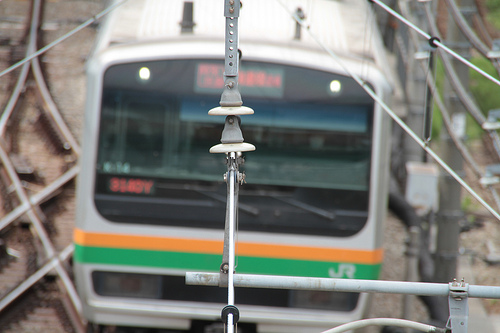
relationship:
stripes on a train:
[83, 224, 381, 298] [65, 19, 435, 331]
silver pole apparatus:
[220, 70, 251, 333] [219, 174, 249, 244]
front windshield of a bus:
[77, 197, 347, 251] [78, 101, 448, 273]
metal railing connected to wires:
[232, 275, 449, 295] [426, 127, 486, 280]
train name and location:
[168, 56, 301, 97] [114, 99, 323, 213]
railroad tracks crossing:
[9, 89, 82, 333] [6, 255, 64, 310]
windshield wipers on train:
[78, 168, 358, 231] [42, 99, 457, 285]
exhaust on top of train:
[291, 51, 303, 91] [82, 171, 392, 333]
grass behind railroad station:
[414, 56, 494, 153] [335, 128, 497, 259]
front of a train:
[80, 38, 373, 331] [129, 243, 253, 280]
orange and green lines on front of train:
[80, 236, 386, 259] [87, 144, 378, 333]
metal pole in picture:
[211, 259, 494, 301] [25, 101, 468, 255]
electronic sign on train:
[177, 57, 279, 101] [102, 99, 379, 257]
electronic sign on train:
[98, 164, 172, 237] [72, 102, 422, 197]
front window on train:
[60, 72, 384, 304] [32, 237, 382, 290]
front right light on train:
[80, 38, 373, 331] [69, 130, 449, 333]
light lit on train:
[135, 64, 152, 81] [70, 1, 394, 331]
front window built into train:
[97, 58, 374, 192] [70, 1, 394, 331]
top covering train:
[86, 0, 395, 93] [70, 1, 394, 331]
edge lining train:
[90, 200, 369, 239] [70, 1, 394, 331]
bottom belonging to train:
[69, 264, 377, 331] [70, 1, 394, 331]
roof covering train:
[84, 0, 401, 94] [70, 1, 394, 331]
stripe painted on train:
[71, 228, 384, 262] [70, 1, 394, 331]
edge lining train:
[376, 80, 389, 279] [70, 1, 394, 331]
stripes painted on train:
[69, 224, 381, 264] [70, 1, 394, 331]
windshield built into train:
[92, 58, 373, 237] [70, 1, 394, 331]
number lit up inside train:
[108, 176, 119, 189] [70, 1, 394, 331]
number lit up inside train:
[119, 177, 128, 192] [70, 1, 394, 331]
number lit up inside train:
[123, 177, 134, 192] [70, 1, 394, 331]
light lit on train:
[328, 77, 342, 95] [70, 1, 394, 331]